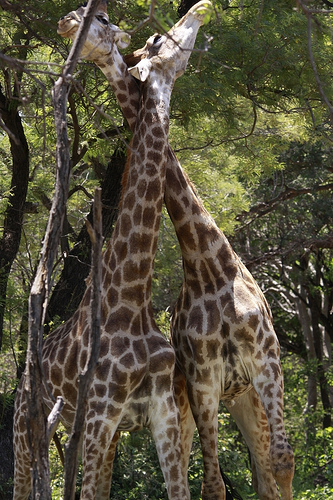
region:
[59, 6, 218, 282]
two giraffes looking up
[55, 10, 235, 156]
two giraffes looking up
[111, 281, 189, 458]
the giraffe's fur is brown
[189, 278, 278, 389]
the giraffe's fur is brown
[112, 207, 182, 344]
the giraffe's fur is brown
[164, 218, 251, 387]
the giraffe's fur is brown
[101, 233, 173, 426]
the giraffe's fur is brown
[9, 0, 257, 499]
white and brown giraffe in forest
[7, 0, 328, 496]
two giraffes with necks intertwined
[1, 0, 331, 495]
green trees in background of forest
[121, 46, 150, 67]
brown horn on giraffe head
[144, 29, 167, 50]
large eye of giraffe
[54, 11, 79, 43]
closed mouth of giraffe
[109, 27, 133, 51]
floppy ear of giraffe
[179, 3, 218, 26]
open mouth of giraffe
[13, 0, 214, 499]
giraffe eating leaves from tree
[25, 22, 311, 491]
two giraffes standing in a forest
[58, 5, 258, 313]
two giraffes crossing their necks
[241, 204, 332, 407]
trees growing behind the giraffes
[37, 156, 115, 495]
broken tree trunk in front of the giraffes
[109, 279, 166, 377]
brown spots on the giraffe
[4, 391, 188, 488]
legs of the giraffe on the left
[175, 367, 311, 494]
legs of the giraffe on the right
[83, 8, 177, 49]
black eyes of the giraffes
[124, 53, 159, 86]
ear of the left giraffe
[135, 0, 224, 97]
a giraffe looking up at the sun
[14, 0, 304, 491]
two tall giraffes reaching upwards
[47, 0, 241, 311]
two giraffes with their necks twisted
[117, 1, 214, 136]
a giraffe reaching towards a tree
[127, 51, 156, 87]
a yellow giraffe ear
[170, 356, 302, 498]
four giraffe legs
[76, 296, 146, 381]
brown spots on a giraffe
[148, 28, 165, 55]
the black eye of a giraffe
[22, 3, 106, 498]
two tree trunks without leaves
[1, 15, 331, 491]
green vegetation in the background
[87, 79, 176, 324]
a long giraffe neck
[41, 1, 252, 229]
two necks of giraffe form a X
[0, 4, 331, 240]
giraffes eating from a tree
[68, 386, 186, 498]
front legs of giraffe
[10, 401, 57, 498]
back legs of giraffe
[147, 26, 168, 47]
black eye of giraffe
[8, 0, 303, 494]
giraffes near a tree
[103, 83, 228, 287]
long necks of giraffe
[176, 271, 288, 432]
muscles of legs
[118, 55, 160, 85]
white ear of giraffe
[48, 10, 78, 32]
nostril of giraffe